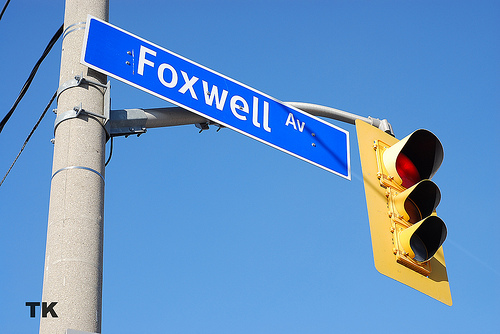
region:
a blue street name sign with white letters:
[80, 18, 355, 178]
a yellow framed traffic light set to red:
[355, 121, 452, 303]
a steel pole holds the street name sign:
[39, 1, 103, 333]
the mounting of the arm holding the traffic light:
[55, 66, 128, 138]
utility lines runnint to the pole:
[0, 0, 66, 188]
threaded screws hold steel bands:
[74, 68, 109, 122]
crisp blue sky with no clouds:
[100, 3, 498, 333]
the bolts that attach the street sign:
[308, 124, 317, 156]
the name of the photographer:
[16, 288, 72, 327]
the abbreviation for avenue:
[283, 110, 317, 136]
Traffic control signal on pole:
[355, 117, 453, 306]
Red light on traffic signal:
[383, 128, 445, 188]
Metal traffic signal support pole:
[111, 99, 391, 143]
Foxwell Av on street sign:
[136, 44, 311, 134]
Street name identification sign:
[76, 13, 352, 183]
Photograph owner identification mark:
[20, 299, 62, 321]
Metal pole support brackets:
[50, 77, 111, 137]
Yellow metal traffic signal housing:
[353, 119, 455, 309]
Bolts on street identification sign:
[120, 48, 135, 68]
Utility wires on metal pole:
[0, 2, 62, 189]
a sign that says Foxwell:
[75, 15, 354, 180]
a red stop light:
[353, 103, 455, 307]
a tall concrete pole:
[34, 0, 115, 332]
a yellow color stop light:
[345, 115, 452, 302]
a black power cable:
[0, 18, 67, 133]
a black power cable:
[0, 80, 64, 195]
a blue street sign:
[80, 10, 351, 177]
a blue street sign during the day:
[75, 10, 345, 175]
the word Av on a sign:
[282, 109, 305, 137]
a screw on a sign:
[125, 47, 133, 57]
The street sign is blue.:
[86, 14, 354, 189]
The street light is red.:
[383, 123, 443, 193]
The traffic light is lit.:
[378, 124, 470, 188]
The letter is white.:
[128, 43, 159, 81]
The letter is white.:
[155, 61, 180, 96]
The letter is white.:
[176, 68, 196, 100]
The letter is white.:
[202, 73, 229, 118]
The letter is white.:
[228, 94, 250, 134]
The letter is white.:
[249, 93, 261, 130]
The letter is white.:
[261, 96, 273, 136]